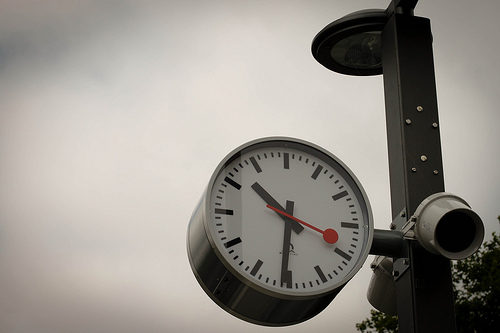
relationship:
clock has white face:
[179, 131, 377, 333] [197, 133, 380, 302]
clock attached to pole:
[179, 131, 377, 333] [377, 0, 458, 333]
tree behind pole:
[359, 231, 499, 326] [377, 0, 458, 333]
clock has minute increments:
[179, 131, 377, 333] [197, 133, 380, 302]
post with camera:
[377, 0, 458, 333] [408, 185, 490, 265]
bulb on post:
[304, 4, 409, 78] [377, 0, 458, 333]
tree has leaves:
[359, 231, 499, 326] [450, 256, 497, 330]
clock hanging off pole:
[179, 131, 377, 333] [377, 0, 458, 333]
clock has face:
[179, 131, 377, 333] [197, 133, 380, 302]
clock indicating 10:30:
[179, 131, 377, 333] [220, 158, 310, 288]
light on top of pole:
[304, 4, 409, 78] [377, 0, 458, 333]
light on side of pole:
[304, 4, 409, 78] [377, 0, 458, 333]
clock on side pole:
[179, 131, 377, 333] [377, 0, 458, 333]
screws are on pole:
[403, 99, 444, 182] [377, 0, 458, 333]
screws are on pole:
[385, 207, 413, 281] [377, 0, 458, 333]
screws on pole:
[406, 149, 440, 179] [377, 0, 458, 333]